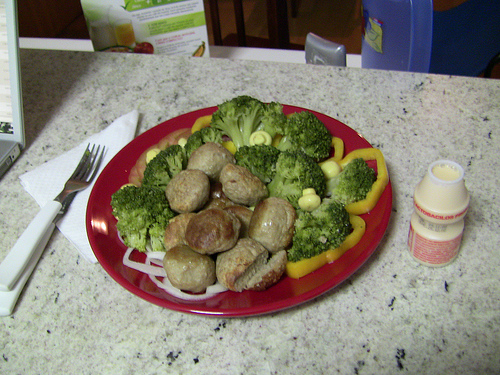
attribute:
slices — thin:
[132, 256, 182, 298]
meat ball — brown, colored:
[182, 203, 242, 253]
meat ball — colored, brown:
[213, 236, 288, 293]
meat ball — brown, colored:
[160, 245, 210, 290]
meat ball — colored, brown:
[162, 210, 192, 248]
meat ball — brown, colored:
[162, 169, 209, 211]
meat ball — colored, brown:
[190, 141, 231, 171]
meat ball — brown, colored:
[219, 160, 270, 202]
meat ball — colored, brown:
[249, 193, 294, 245]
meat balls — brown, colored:
[159, 138, 296, 294]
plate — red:
[83, 95, 393, 315]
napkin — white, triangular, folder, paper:
[16, 104, 144, 264]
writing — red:
[407, 225, 462, 263]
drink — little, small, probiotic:
[404, 152, 472, 268]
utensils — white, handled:
[5, 138, 106, 311]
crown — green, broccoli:
[110, 183, 173, 252]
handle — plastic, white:
[4, 200, 61, 289]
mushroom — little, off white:
[246, 130, 272, 148]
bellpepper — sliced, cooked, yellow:
[331, 144, 390, 212]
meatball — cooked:
[246, 194, 296, 252]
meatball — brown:
[183, 206, 242, 255]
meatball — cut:
[213, 236, 288, 295]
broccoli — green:
[109, 182, 172, 253]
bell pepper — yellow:
[336, 145, 390, 215]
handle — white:
[1, 199, 63, 291]